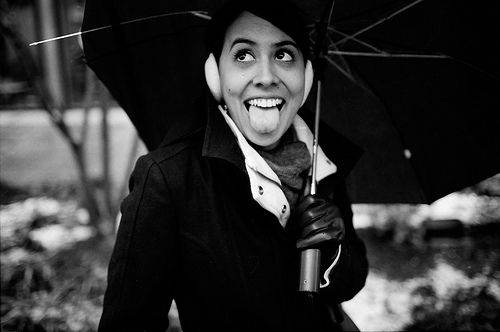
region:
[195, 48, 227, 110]
White ear muffs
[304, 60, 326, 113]
White ear muffs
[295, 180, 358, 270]
Black lether like glove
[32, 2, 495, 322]
WOman holding an umbrella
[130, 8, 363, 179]
Woman sticking her tounge out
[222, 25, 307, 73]
Womans eyes looking to the side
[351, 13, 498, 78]
Metal wires on the umbrella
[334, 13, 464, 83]
Metal bones of the umbrella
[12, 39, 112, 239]
Snow covering tree and bushes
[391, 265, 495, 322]
Snow covering the ground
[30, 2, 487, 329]
a woman carrying an umbrella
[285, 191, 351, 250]
the woman is wearing a glove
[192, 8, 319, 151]
the woman is smiling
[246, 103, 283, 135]
her tongue is sticking out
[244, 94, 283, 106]
the woman's teeth are white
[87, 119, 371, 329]
the woman is wearing a dark jacket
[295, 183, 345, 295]
the hand holding the umbrella handle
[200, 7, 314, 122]
the woman is wearing earmuffs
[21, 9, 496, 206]
the umbrella is dark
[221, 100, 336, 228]
she is wearing a scarf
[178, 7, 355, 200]
a woman sticking out her tongue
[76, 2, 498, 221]
a black umbrella carried by woman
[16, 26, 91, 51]
one spoke of the umbrella sticking out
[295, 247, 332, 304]
round handle base of umbrella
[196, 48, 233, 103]
white earmuffs worn by woman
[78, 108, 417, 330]
black jacket with white collar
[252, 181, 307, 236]
two snaps on collar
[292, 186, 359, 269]
black glove on hand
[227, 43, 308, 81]
eyes rolled up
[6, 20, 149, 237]
a small tree behind woman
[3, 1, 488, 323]
the picture is black and white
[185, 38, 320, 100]
the woman is wearing ear muffs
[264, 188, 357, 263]
the woman is wearing gloves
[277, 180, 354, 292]
the glove is dark colored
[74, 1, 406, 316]
the woman is under an umbrella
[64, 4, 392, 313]
the woman is holding an umbrella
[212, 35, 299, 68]
the eyes are looking up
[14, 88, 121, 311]
the background is blurry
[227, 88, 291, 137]
woman`s mouth is open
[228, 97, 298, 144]
the woman`s tongue is out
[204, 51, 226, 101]
white muffs on ear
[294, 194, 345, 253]
shiny black leather glove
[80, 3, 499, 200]
fabric and metal umbrella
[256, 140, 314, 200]
scarf wrapped around neck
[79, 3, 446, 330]
woman holding black umbrella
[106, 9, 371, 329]
woman wearing black trench coat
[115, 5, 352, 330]
woman with tounge out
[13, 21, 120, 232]
tree with no leaves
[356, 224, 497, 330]
pond next to plants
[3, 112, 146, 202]
concrete wall by tree